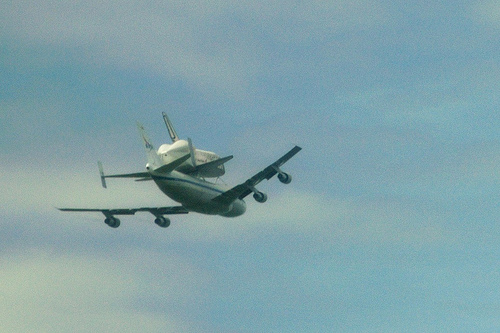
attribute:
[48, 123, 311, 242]
plane — blue, white, large, flying, grey, present, sharp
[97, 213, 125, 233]
engine — large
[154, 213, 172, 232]
engine — large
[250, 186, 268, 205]
engine — large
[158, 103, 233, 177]
space shuttle — white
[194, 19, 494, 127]
sky — blue, gray, cloudy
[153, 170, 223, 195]
strip — blue, dark